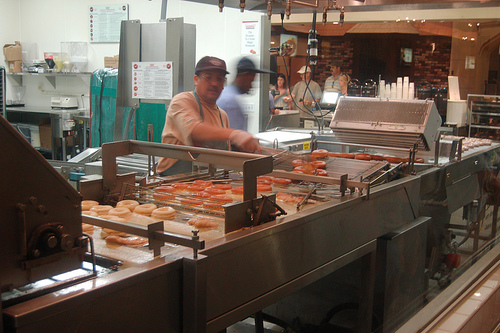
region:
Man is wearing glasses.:
[194, 67, 232, 89]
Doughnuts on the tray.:
[278, 136, 368, 187]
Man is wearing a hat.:
[236, 55, 279, 85]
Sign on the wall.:
[81, 4, 131, 38]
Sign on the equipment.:
[125, 57, 181, 98]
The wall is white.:
[15, 9, 90, 44]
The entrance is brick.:
[316, 41, 446, 85]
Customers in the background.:
[271, 61, 351, 104]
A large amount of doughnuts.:
[51, 146, 404, 261]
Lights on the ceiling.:
[404, 15, 485, 45]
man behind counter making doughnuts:
[155, 54, 268, 178]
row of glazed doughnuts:
[115, 197, 176, 219]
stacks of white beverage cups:
[376, 74, 417, 106]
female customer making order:
[267, 70, 299, 117]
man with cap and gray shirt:
[290, 63, 325, 118]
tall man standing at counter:
[317, 54, 352, 114]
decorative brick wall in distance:
[309, 28, 456, 114]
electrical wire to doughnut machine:
[273, 32, 337, 139]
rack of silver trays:
[462, 88, 499, 150]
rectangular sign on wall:
[127, 58, 175, 105]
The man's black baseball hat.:
[196, 55, 230, 73]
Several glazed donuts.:
[155, 180, 228, 207]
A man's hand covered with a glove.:
[231, 130, 261, 154]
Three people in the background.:
[274, 61, 345, 106]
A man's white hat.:
[296, 63, 311, 73]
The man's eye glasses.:
[201, 71, 227, 85]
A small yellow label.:
[302, 140, 312, 150]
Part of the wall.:
[322, 43, 342, 61]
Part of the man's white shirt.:
[171, 107, 190, 128]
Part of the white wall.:
[27, 13, 71, 29]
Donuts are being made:
[57, 125, 498, 272]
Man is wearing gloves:
[227, 124, 265, 153]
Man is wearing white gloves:
[227, 124, 269, 157]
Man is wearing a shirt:
[153, 88, 233, 172]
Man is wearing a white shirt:
[150, 87, 237, 172]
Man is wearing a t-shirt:
[154, 85, 236, 172]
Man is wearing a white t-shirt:
[150, 86, 235, 173]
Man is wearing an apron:
[156, 86, 236, 176]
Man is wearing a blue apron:
[156, 87, 233, 174]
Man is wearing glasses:
[187, 71, 235, 86]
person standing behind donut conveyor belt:
[169, 49, 257, 166]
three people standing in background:
[268, 61, 346, 114]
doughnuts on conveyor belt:
[77, 142, 413, 249]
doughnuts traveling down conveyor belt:
[92, 142, 412, 260]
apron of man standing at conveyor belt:
[161, 102, 231, 163]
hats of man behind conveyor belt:
[190, 54, 267, 75]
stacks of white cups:
[375, 71, 415, 98]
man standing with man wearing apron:
[220, 53, 262, 123]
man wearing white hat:
[293, 65, 318, 111]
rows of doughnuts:
[85, 141, 355, 273]